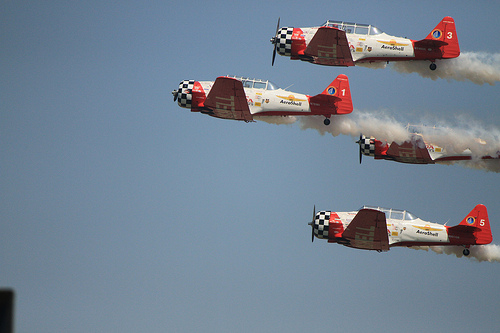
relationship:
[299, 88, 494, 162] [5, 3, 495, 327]
clouds in sky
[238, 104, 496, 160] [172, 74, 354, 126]
smoke behind airplane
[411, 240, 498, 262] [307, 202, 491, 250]
smoke behind plane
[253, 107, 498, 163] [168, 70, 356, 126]
smoke coming from plane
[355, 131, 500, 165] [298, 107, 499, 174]
airplane covered with smoke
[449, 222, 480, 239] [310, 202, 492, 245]
stabilizer of plane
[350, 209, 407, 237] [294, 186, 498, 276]
wing of plane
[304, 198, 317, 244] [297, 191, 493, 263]
propeller of plane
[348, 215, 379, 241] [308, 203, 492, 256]
number on airplane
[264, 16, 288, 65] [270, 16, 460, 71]
propeller on airplane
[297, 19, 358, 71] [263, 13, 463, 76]
wing on plane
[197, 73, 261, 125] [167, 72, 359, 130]
wing on plane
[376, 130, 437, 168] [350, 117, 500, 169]
wing on plane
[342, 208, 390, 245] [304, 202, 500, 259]
wing on plane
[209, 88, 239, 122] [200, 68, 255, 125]
writing on wings